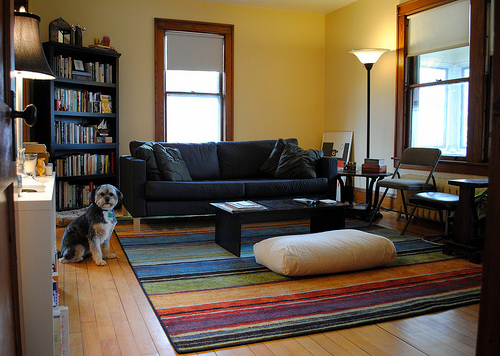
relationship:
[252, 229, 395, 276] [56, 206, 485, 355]
pillow on floor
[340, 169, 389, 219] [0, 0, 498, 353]
side table in living room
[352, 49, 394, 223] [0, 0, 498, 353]
floor lamp in living room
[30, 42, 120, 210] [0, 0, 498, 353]
book shelf in living room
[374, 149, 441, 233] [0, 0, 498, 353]
folding chair in living room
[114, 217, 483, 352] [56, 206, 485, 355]
rug on floor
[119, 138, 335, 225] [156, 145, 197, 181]
couch with pillow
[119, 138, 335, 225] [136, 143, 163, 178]
couch with pillow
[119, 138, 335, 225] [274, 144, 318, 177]
couch with pillow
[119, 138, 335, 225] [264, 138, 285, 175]
couch with pillow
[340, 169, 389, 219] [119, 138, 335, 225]
side table next to couch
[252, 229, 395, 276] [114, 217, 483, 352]
pillow on rug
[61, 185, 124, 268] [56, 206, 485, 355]
dog sitting on floor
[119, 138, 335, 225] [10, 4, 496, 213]
couch near wall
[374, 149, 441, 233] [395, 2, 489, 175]
folding chair near window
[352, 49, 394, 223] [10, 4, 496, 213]
floor lamp near wall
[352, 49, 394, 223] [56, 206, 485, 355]
floor lamp on floor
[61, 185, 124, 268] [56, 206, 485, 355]
dog on floor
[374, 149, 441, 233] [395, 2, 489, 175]
folding chair by window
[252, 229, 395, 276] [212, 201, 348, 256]
pillow in front of center table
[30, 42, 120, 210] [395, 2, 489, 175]
book shelf along window